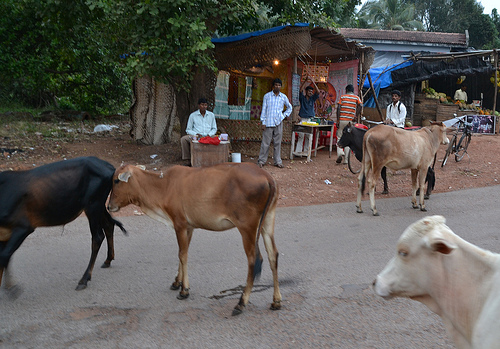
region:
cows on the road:
[5, 120, 496, 343]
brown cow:
[98, 155, 291, 325]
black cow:
[0, 156, 120, 301]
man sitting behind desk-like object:
[165, 92, 236, 167]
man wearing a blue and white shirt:
[253, 72, 298, 128]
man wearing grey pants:
[255, 117, 290, 168]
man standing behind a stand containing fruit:
[400, 62, 497, 137]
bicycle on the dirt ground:
[436, 111, 486, 171]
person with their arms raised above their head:
[291, 62, 326, 112]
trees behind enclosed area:
[0, 0, 380, 132]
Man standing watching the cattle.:
[253, 78, 292, 168]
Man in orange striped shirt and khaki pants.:
[331, 83, 358, 155]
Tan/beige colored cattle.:
[364, 210, 498, 347]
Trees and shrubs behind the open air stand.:
[14, 4, 194, 116]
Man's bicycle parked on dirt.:
[439, 125, 474, 162]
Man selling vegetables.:
[453, 82, 473, 104]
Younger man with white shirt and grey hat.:
[381, 87, 410, 127]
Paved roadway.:
[0, 181, 499, 345]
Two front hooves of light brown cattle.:
[164, 277, 190, 300]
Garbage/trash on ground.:
[19, 125, 78, 157]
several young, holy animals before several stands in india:
[1, 0, 498, 347]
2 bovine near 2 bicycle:
[338, 112, 475, 217]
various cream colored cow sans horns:
[359, 210, 498, 347]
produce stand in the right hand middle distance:
[387, 52, 497, 129]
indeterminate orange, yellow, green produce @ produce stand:
[412, 80, 497, 120]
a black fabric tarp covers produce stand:
[382, 47, 498, 84]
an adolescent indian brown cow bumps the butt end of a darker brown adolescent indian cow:
[0, 149, 302, 320]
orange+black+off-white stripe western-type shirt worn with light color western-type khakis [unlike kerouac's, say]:
[324, 90, 365, 165]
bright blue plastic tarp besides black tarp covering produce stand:
[345, 53, 419, 112]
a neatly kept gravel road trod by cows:
[0, 180, 499, 347]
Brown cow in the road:
[97, 141, 305, 324]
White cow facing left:
[363, 203, 498, 345]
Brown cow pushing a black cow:
[102, 151, 299, 329]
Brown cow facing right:
[350, 114, 459, 217]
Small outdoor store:
[161, 9, 376, 188]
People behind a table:
[291, 74, 327, 164]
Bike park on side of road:
[433, 106, 483, 170]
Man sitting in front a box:
[174, 88, 234, 162]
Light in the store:
[265, 51, 285, 71]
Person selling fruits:
[421, 80, 498, 122]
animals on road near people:
[41, 11, 466, 324]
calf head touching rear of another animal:
[55, 146, 175, 251]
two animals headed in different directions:
[330, 102, 460, 217]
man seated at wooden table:
[160, 75, 245, 167]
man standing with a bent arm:
[240, 66, 295, 176]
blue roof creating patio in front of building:
[122, 15, 372, 157]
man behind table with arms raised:
[287, 65, 334, 170]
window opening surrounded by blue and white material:
[207, 65, 257, 125]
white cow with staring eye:
[355, 200, 492, 336]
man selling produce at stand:
[406, 42, 496, 134]